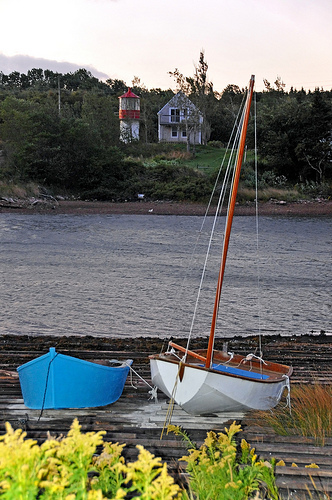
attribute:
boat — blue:
[164, 76, 293, 408]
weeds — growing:
[253, 374, 330, 453]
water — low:
[3, 211, 331, 334]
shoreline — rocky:
[27, 196, 332, 227]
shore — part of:
[4, 189, 331, 221]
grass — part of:
[237, 180, 304, 207]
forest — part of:
[5, 49, 328, 206]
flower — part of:
[298, 463, 327, 497]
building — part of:
[149, 85, 216, 143]